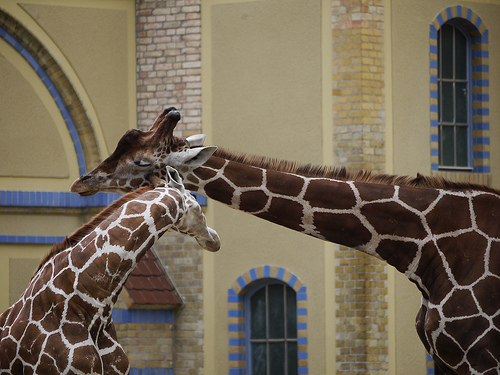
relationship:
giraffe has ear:
[68, 111, 499, 369] [174, 147, 220, 169]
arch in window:
[4, 5, 112, 195] [0, 1, 139, 222]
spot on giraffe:
[430, 223, 491, 290] [68, 111, 499, 369]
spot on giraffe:
[422, 184, 469, 234] [68, 111, 499, 369]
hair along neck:
[216, 140, 478, 198] [205, 140, 436, 279]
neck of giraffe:
[205, 140, 436, 279] [68, 111, 499, 369]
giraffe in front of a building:
[2, 164, 225, 373] [2, 1, 498, 371]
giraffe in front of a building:
[68, 111, 499, 369] [2, 1, 498, 371]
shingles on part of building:
[117, 232, 189, 309] [2, 1, 498, 371]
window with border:
[237, 277, 312, 369] [217, 264, 313, 373]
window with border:
[422, 5, 496, 178] [426, 12, 495, 177]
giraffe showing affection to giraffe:
[2, 164, 225, 373] [68, 111, 499, 369]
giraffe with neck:
[68, 111, 499, 369] [190, 140, 417, 261]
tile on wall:
[122, 251, 185, 311] [1, 6, 499, 369]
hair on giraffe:
[214, 146, 500, 195] [68, 111, 499, 369]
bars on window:
[246, 282, 296, 374] [246, 282, 296, 373]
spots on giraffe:
[383, 188, 496, 259] [68, 111, 499, 369]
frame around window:
[225, 263, 311, 373] [246, 282, 296, 373]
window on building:
[242, 279, 294, 373] [2, 1, 498, 371]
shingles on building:
[123, 247, 184, 306] [2, 1, 498, 371]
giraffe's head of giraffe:
[68, 106, 219, 197] [68, 111, 499, 369]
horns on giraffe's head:
[145, 101, 184, 153] [68, 106, 219, 197]